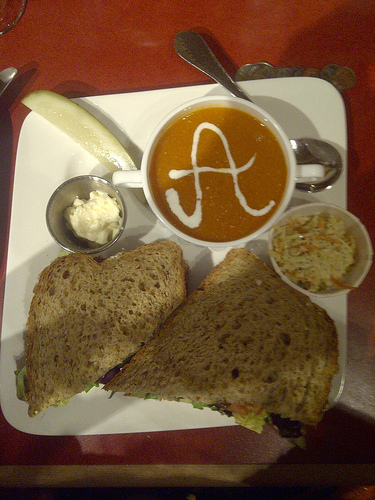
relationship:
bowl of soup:
[112, 95, 296, 248] [145, 105, 286, 242]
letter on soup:
[165, 122, 275, 229] [145, 105, 286, 242]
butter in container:
[63, 190, 121, 249] [47, 173, 127, 254]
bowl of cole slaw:
[268, 203, 373, 298] [270, 211, 360, 292]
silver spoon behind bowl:
[175, 29, 341, 192] [112, 95, 296, 248]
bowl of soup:
[112, 95, 296, 248] [137, 102, 303, 246]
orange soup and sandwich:
[149, 106, 288, 244] [13, 238, 340, 451]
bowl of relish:
[311, 204, 373, 277] [267, 203, 374, 306]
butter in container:
[62, 185, 121, 249] [45, 175, 127, 253]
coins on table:
[234, 53, 359, 100] [0, 0, 375, 488]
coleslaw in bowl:
[268, 202, 369, 293] [268, 203, 373, 298]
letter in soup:
[160, 123, 269, 223] [144, 110, 303, 232]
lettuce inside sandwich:
[218, 387, 278, 436] [13, 238, 340, 451]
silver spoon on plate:
[175, 29, 341, 192] [12, 77, 350, 448]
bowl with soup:
[112, 95, 296, 248] [145, 105, 286, 242]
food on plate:
[19, 88, 370, 430] [12, 77, 350, 448]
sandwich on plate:
[13, 222, 361, 449] [12, 77, 350, 448]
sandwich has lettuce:
[13, 238, 340, 451] [228, 402, 268, 436]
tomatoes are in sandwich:
[220, 400, 262, 420] [13, 238, 340, 451]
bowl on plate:
[111, 95, 296, 248] [12, 77, 350, 448]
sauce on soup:
[164, 119, 274, 229] [145, 105, 286, 242]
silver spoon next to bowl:
[175, 29, 341, 192] [112, 95, 296, 248]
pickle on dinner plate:
[21, 89, 145, 206] [0, 75, 348, 437]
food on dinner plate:
[19, 88, 370, 430] [27, 136, 59, 171]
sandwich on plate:
[13, 238, 340, 451] [12, 77, 350, 448]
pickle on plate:
[10, 73, 164, 189] [12, 77, 350, 448]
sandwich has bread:
[13, 238, 340, 451] [111, 246, 348, 438]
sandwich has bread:
[13, 238, 340, 451] [24, 243, 187, 417]